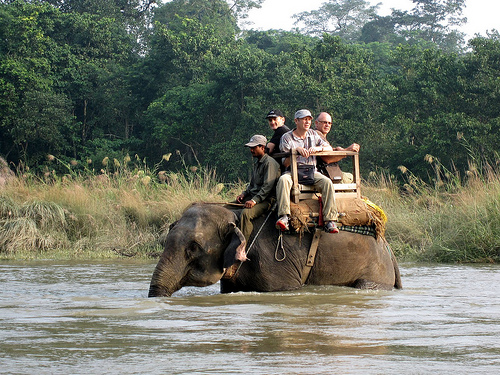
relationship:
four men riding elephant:
[248, 107, 355, 234] [118, 184, 416, 308]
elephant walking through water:
[146, 198, 402, 298] [3, 297, 483, 371]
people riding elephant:
[235, 104, 364, 233] [146, 198, 402, 298]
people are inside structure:
[235, 104, 364, 233] [279, 141, 365, 205]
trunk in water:
[146, 255, 186, 297] [0, 260, 498, 374]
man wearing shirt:
[265, 109, 292, 173] [263, 124, 293, 153]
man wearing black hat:
[265, 109, 292, 173] [265, 109, 283, 119]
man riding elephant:
[223, 134, 281, 251] [146, 198, 402, 298]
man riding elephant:
[278, 106, 338, 240] [146, 198, 402, 298]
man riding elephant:
[265, 109, 292, 173] [146, 198, 402, 298]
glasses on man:
[318, 118, 335, 128] [313, 104, 344, 150]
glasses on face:
[318, 118, 335, 128] [318, 113, 336, 133]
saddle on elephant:
[242, 137, 401, 240] [146, 198, 402, 298]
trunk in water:
[133, 244, 194, 304] [390, 295, 487, 357]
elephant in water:
[146, 198, 402, 298] [3, 297, 483, 371]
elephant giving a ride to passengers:
[90, 167, 427, 338] [265, 99, 354, 237]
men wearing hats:
[228, 106, 365, 266] [230, 101, 314, 150]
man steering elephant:
[223, 134, 281, 251] [146, 198, 402, 298]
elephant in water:
[146, 198, 402, 298] [0, 260, 498, 374]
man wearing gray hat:
[275, 109, 340, 238] [291, 107, 312, 120]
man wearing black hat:
[254, 103, 296, 163] [258, 104, 285, 119]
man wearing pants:
[225, 130, 287, 252] [223, 197, 278, 247]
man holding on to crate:
[312, 117, 369, 178] [268, 142, 371, 200]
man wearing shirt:
[223, 134, 281, 251] [235, 162, 280, 208]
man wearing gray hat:
[283, 110, 348, 224] [294, 109, 313, 120]